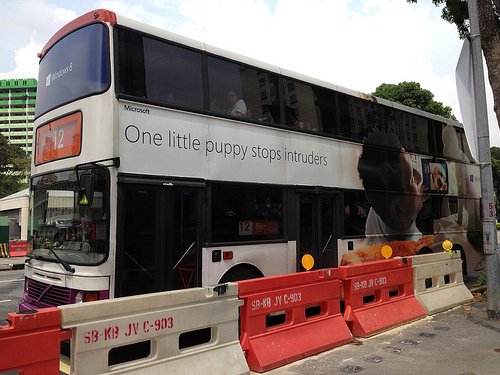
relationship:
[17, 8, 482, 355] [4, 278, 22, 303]
bus parked on street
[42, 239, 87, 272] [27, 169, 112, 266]
windshield wiper on windshield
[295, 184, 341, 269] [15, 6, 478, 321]
door on bus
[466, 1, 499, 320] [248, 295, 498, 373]
pole on sidewalk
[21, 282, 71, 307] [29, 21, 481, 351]
grill on bus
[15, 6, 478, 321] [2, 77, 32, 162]
bus behind building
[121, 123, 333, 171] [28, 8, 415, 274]
writing on bus.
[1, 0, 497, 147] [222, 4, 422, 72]
clouds in sky.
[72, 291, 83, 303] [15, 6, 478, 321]
headlights on bus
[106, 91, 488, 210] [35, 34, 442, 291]
advert on bus